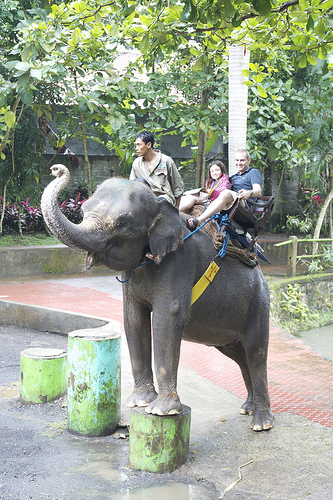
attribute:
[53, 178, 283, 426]
elephant — gray, standing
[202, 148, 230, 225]
person — sitting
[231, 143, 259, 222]
person — sitting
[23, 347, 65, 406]
post — green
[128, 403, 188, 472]
post — green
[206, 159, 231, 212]
daughter — smiling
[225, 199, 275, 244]
bench — small, wooden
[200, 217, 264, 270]
blanket — folded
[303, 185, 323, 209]
flower — growing, red, pink, pretty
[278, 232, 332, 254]
rail — wooden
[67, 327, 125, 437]
post — green, tallest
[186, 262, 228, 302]
strap — yellow, thick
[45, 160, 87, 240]
trunk — upturned, long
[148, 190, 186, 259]
ear — large, floppy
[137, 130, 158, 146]
hair — dark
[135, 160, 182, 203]
shirt — brown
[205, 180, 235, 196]
top — pink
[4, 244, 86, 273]
wall — concrete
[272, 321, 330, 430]
tiles — red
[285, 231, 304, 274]
fence post — brown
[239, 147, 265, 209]
man — smiling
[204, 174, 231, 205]
coat — pink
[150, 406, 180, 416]
toe nails — white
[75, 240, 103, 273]
mouth — open